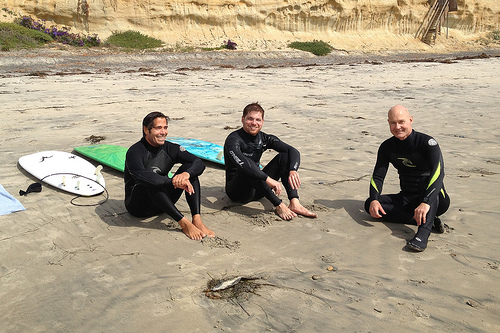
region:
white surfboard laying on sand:
[16, 147, 104, 195]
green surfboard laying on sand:
[73, 142, 129, 171]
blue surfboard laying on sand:
[166, 136, 224, 168]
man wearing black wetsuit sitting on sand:
[363, 106, 450, 253]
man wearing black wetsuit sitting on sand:
[222, 102, 317, 221]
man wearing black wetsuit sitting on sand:
[125, 112, 216, 242]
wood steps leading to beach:
[416, 2, 450, 45]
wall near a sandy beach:
[0, 2, 499, 57]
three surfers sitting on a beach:
[123, 106, 452, 253]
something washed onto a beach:
[202, 271, 274, 300]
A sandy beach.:
[0, 59, 499, 329]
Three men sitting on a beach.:
[120, 99, 452, 254]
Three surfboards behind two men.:
[19, 100, 318, 246]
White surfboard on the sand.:
[6, 148, 113, 210]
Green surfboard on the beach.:
[70, 145, 137, 170]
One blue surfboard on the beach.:
[166, 135, 232, 162]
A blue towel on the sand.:
[0, 179, 24, 220]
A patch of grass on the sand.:
[284, 37, 346, 59]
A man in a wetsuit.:
[365, 103, 450, 255]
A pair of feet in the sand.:
[177, 210, 215, 244]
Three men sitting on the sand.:
[108, 97, 437, 240]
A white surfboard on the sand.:
[32, 137, 93, 205]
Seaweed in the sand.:
[202, 255, 263, 301]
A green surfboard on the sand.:
[85, 131, 131, 167]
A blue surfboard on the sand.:
[175, 133, 226, 169]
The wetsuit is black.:
[127, 143, 192, 224]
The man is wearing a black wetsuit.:
[367, 101, 458, 247]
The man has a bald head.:
[387, 100, 405, 118]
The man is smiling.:
[150, 116, 203, 149]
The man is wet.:
[232, 96, 297, 216]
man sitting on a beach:
[356, 100, 457, 277]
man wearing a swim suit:
[361, 105, 461, 271]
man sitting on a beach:
[222, 92, 313, 234]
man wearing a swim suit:
[212, 96, 322, 228]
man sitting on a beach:
[140, 106, 207, 242]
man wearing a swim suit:
[120, 106, 210, 231]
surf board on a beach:
[20, 132, 112, 205]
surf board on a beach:
[93, 136, 113, 168]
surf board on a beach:
[191, 126, 218, 156]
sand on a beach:
[46, 243, 113, 296]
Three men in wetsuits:
[121, 100, 451, 249]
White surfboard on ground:
[17, 151, 104, 200]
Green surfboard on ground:
[77, 141, 126, 171]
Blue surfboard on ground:
[167, 136, 226, 165]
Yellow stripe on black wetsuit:
[428, 156, 439, 190]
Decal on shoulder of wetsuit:
[426, 137, 436, 147]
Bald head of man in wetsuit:
[387, 106, 413, 137]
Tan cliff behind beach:
[0, 2, 498, 52]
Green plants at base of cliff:
[102, 30, 167, 48]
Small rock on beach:
[323, 262, 336, 272]